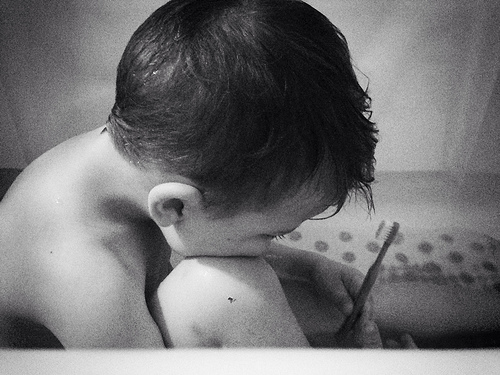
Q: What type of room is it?
A: It is a bathroom.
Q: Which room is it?
A: It is a bathroom.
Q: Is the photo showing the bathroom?
A: Yes, it is showing the bathroom.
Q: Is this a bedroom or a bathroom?
A: It is a bathroom.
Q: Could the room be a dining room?
A: No, it is a bathroom.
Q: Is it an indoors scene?
A: Yes, it is indoors.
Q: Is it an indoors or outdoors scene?
A: It is indoors.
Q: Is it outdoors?
A: No, it is indoors.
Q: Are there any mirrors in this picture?
A: No, there are no mirrors.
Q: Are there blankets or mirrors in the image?
A: No, there are no mirrors or blankets.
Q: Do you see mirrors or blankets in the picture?
A: No, there are no mirrors or blankets.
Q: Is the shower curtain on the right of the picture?
A: Yes, the shower curtain is on the right of the image.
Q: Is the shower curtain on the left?
A: No, the shower curtain is on the right of the image.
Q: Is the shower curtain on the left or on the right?
A: The shower curtain is on the right of the image.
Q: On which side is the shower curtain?
A: The shower curtain is on the right of the image.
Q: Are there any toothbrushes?
A: Yes, there is a toothbrush.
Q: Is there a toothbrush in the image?
A: Yes, there is a toothbrush.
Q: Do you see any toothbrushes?
A: Yes, there is a toothbrush.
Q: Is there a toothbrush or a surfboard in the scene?
A: Yes, there is a toothbrush.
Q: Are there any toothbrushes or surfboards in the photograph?
A: Yes, there is a toothbrush.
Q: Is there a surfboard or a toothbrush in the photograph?
A: Yes, there is a toothbrush.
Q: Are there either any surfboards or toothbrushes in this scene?
A: Yes, there is a toothbrush.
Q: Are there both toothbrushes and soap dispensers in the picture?
A: No, there is a toothbrush but no soap dispensers.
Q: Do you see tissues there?
A: No, there are no tissues.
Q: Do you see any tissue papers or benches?
A: No, there are no tissue papers or benches.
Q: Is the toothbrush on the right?
A: Yes, the toothbrush is on the right of the image.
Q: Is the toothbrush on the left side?
A: No, the toothbrush is on the right of the image.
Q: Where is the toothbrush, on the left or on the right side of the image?
A: The toothbrush is on the right of the image.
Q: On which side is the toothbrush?
A: The toothbrush is on the right of the image.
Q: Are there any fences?
A: No, there are no fences.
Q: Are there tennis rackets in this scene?
A: No, there are no tennis rackets.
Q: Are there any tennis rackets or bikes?
A: No, there are no tennis rackets or bikes.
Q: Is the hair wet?
A: Yes, the hair is wet.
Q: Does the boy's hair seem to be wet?
A: Yes, the hair is wet.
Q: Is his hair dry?
A: No, the hair is wet.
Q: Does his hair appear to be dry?
A: No, the hair is wet.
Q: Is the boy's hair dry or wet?
A: The hair is wet.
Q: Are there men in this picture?
A: No, there are no men.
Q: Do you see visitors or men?
A: No, there are no men or visitors.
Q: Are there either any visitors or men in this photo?
A: No, there are no men or visitors.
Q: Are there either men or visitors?
A: No, there are no men or visitors.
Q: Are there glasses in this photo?
A: No, there are no glasses.